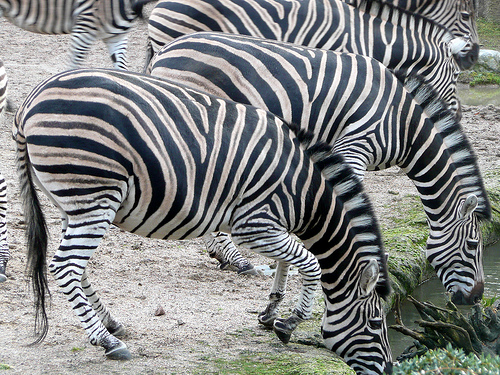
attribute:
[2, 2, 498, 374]
animals — a group, drinking water, drinking, thirsty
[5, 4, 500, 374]
photo — a field, during the day time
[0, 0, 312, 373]
dirt — gray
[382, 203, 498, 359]
spot — a river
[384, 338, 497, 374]
patch — small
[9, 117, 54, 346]
tail — black, long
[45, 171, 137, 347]
leg — bent, curled, striped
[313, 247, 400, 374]
head — bent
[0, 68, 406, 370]
zebra — black, white, in photo, drinking, walking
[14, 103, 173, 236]
stripe — black, large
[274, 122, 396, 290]
mane — striped